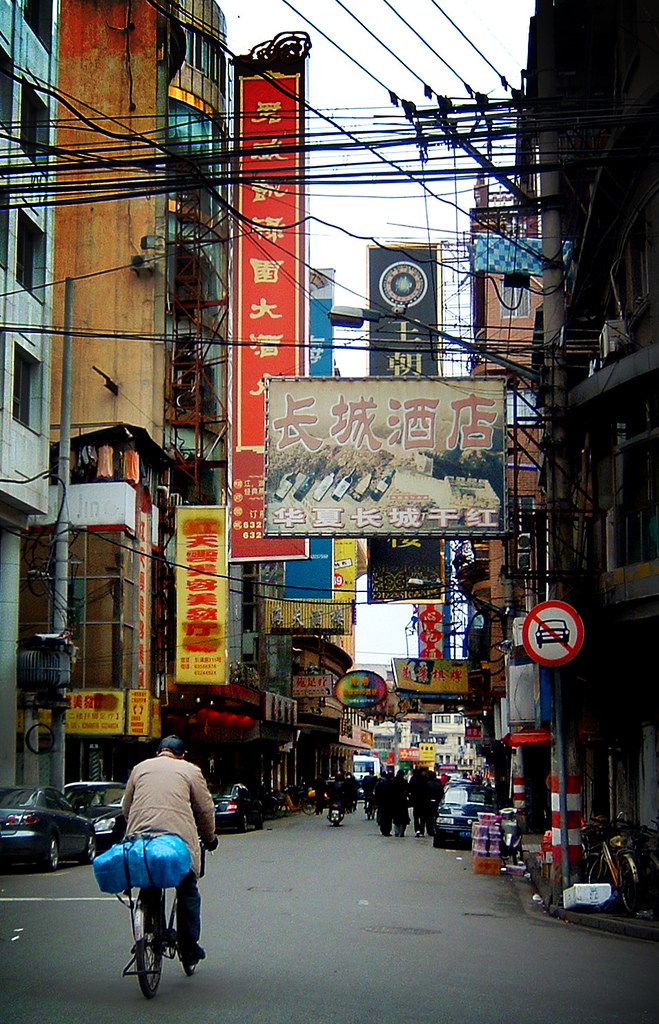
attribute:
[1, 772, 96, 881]
car — gray